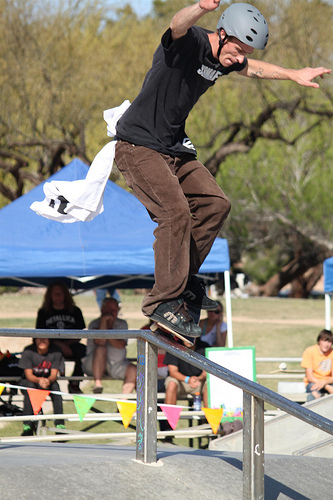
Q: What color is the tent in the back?
A: The tent is blue.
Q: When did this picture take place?
A: It took place in the day time.